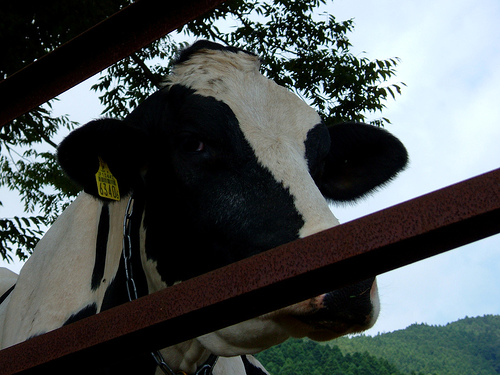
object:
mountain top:
[374, 313, 499, 374]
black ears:
[54, 116, 147, 206]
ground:
[390, 0, 499, 136]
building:
[0, 0, 219, 131]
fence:
[1, 166, 500, 375]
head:
[54, 38, 408, 358]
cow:
[0, 39, 410, 375]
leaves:
[87, 0, 409, 130]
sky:
[1, 0, 499, 341]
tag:
[96, 160, 121, 202]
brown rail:
[0, 167, 500, 375]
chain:
[120, 192, 220, 375]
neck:
[95, 176, 193, 364]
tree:
[347, 306, 500, 375]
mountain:
[249, 315, 500, 373]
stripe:
[160, 57, 342, 239]